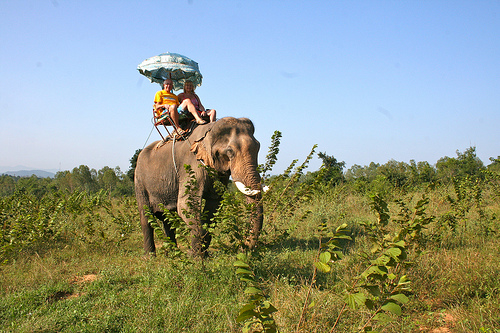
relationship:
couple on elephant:
[156, 78, 217, 136] [134, 116, 270, 263]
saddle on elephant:
[152, 107, 197, 138] [134, 116, 270, 263]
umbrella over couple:
[136, 53, 203, 90] [156, 78, 217, 136]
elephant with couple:
[134, 116, 270, 263] [156, 78, 217, 136]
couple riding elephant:
[156, 78, 217, 136] [134, 116, 270, 263]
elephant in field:
[134, 116, 270, 263] [6, 175, 499, 331]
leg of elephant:
[178, 182, 205, 261] [134, 116, 270, 263]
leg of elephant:
[133, 191, 158, 256] [134, 116, 270, 263]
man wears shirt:
[155, 79, 203, 131] [155, 90, 179, 107]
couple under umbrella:
[156, 78, 217, 136] [136, 53, 203, 90]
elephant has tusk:
[134, 116, 270, 263] [234, 181, 260, 196]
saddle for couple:
[152, 107, 197, 138] [156, 78, 217, 136]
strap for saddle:
[172, 131, 178, 173] [152, 107, 197, 138]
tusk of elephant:
[234, 181, 260, 196] [134, 116, 270, 263]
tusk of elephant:
[262, 183, 269, 193] [134, 116, 270, 263]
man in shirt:
[155, 79, 203, 131] [155, 90, 179, 107]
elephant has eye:
[134, 116, 270, 263] [229, 147, 234, 155]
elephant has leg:
[134, 116, 270, 263] [178, 182, 205, 261]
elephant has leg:
[134, 116, 270, 263] [133, 191, 158, 256]